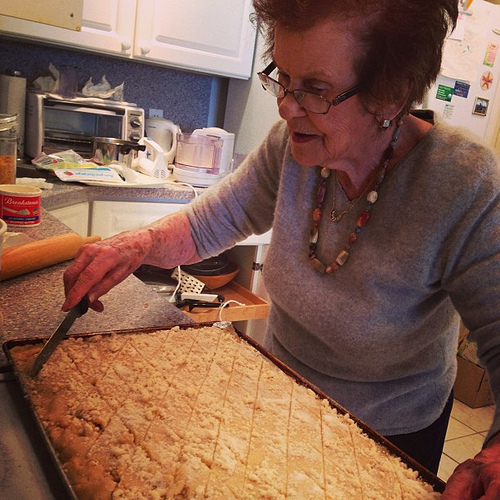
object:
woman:
[62, 1, 500, 497]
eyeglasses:
[256, 60, 374, 114]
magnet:
[452, 80, 472, 99]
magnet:
[436, 86, 455, 101]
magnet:
[480, 72, 492, 89]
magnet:
[440, 104, 454, 119]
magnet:
[470, 97, 491, 118]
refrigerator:
[419, 31, 500, 150]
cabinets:
[138, 0, 255, 79]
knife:
[27, 301, 87, 378]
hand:
[439, 440, 499, 499]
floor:
[430, 397, 498, 479]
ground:
[438, 146, 451, 166]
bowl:
[180, 259, 241, 290]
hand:
[59, 230, 147, 313]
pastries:
[8, 323, 443, 499]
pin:
[1, 230, 101, 283]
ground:
[450, 393, 486, 444]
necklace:
[307, 114, 406, 273]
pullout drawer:
[146, 272, 269, 323]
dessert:
[108, 372, 228, 472]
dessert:
[118, 341, 342, 497]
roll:
[3, 69, 27, 159]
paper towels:
[2, 71, 27, 158]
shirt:
[180, 108, 500, 449]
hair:
[247, 0, 458, 122]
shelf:
[163, 285, 273, 322]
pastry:
[22, 345, 424, 497]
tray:
[2, 317, 447, 498]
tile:
[463, 412, 480, 440]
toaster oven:
[22, 87, 145, 159]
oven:
[23, 91, 148, 163]